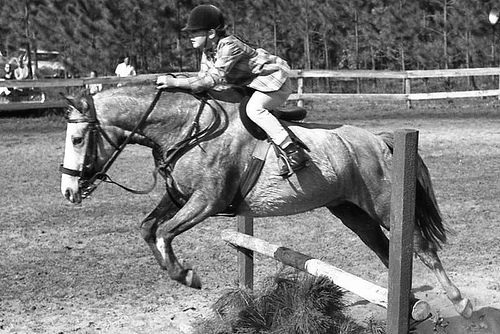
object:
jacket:
[183, 35, 293, 93]